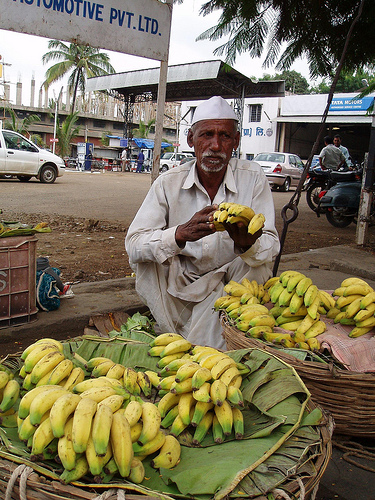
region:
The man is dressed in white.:
[119, 90, 286, 350]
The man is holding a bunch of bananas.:
[120, 92, 288, 356]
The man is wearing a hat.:
[124, 89, 285, 359]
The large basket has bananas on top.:
[206, 261, 374, 444]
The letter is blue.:
[92, 0, 104, 25]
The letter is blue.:
[106, 1, 118, 29]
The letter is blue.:
[124, 7, 136, 31]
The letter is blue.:
[149, 14, 161, 38]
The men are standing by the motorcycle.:
[295, 117, 373, 232]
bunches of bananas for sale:
[7, 317, 286, 495]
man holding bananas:
[133, 96, 278, 267]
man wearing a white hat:
[181, 92, 241, 171]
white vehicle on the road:
[0, 130, 68, 179]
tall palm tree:
[45, 31, 111, 159]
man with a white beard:
[178, 91, 245, 178]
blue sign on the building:
[326, 90, 373, 114]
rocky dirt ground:
[46, 218, 116, 270]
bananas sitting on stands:
[13, 266, 373, 488]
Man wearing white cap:
[167, 90, 272, 249]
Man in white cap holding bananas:
[124, 92, 274, 253]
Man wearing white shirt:
[120, 95, 276, 266]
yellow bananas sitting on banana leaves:
[0, 330, 278, 483]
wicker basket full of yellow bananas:
[211, 265, 369, 436]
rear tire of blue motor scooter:
[310, 172, 370, 228]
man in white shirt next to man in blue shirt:
[308, 124, 368, 184]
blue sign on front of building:
[317, 90, 368, 180]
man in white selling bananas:
[98, 97, 356, 465]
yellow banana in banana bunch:
[50, 395, 65, 427]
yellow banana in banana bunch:
[110, 414, 133, 471]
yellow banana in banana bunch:
[125, 404, 137, 424]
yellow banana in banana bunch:
[138, 402, 157, 441]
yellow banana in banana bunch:
[161, 435, 182, 474]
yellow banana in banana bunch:
[175, 396, 188, 419]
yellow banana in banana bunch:
[218, 409, 234, 432]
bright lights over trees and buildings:
[1, 0, 373, 125]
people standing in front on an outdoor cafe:
[68, 130, 152, 175]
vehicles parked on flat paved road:
[0, 126, 360, 245]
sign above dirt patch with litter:
[1, 2, 170, 340]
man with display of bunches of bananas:
[6, 96, 372, 496]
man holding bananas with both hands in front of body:
[125, 94, 282, 346]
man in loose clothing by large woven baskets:
[127, 94, 283, 344]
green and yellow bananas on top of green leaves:
[4, 325, 317, 494]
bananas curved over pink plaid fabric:
[214, 266, 373, 370]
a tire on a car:
[38, 157, 69, 198]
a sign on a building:
[334, 88, 367, 113]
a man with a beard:
[199, 124, 240, 179]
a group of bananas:
[0, 313, 254, 490]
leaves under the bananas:
[35, 314, 315, 498]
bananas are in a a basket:
[208, 260, 373, 440]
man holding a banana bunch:
[117, 89, 280, 337]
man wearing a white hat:
[172, 94, 244, 131]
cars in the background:
[131, 122, 325, 196]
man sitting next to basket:
[124, 69, 282, 365]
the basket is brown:
[218, 315, 372, 445]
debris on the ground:
[13, 202, 129, 288]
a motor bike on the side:
[298, 163, 360, 228]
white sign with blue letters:
[0, 0, 175, 62]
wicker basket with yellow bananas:
[0, 332, 331, 497]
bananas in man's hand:
[211, 201, 266, 251]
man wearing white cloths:
[124, 93, 281, 349]